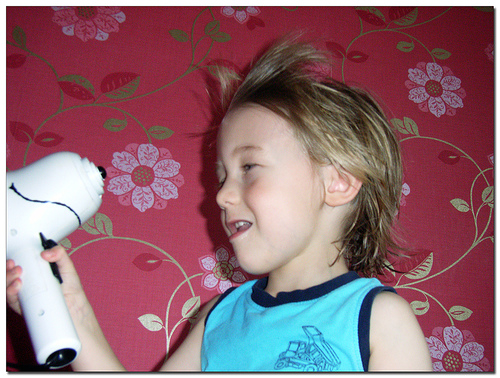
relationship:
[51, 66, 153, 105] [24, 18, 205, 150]
leaves on wall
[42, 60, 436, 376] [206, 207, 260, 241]
boy has mouth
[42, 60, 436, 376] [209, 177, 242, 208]
boy has nose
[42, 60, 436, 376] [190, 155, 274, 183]
boy has eyes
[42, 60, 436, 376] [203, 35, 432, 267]
boy has hair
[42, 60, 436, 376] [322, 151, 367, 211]
boy has ear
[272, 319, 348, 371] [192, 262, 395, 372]
design on shirt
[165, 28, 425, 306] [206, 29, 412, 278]
child has hair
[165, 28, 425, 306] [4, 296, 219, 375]
child casting shadow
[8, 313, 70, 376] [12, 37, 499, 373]
shadow on cloth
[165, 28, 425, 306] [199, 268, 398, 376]
child wearing tank top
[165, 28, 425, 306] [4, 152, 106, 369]
child holding hair dryer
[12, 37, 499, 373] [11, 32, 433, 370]
cloth behind child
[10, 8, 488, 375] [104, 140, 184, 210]
surface has flower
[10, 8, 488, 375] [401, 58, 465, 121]
surface has flower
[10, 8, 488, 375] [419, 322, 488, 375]
surface has flower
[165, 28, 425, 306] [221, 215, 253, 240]
child has mouth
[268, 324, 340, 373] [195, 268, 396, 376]
drawing on shirt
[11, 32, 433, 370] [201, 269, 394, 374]
child wearing t-shirt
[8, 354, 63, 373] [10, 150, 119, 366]
wire of hair dryer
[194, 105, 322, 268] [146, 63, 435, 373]
face of child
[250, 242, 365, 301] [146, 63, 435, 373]
neck of child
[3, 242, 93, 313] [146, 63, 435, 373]
hands of child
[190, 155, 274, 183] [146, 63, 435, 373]
eyes of child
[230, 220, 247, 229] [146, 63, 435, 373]
teeth of child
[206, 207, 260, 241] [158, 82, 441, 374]
mouth of child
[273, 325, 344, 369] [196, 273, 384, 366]
truck on shirt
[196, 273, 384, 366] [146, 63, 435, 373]
shirt of child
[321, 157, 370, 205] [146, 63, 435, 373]
ear of child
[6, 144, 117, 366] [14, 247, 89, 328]
dryer in hand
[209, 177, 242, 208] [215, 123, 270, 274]
nose on face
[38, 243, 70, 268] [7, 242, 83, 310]
thumb on hand